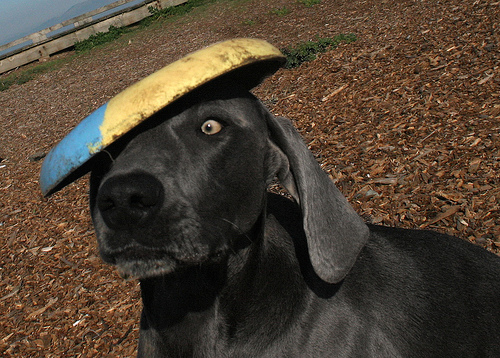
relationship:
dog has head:
[84, 81, 499, 357] [85, 92, 374, 285]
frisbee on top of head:
[38, 37, 285, 201] [85, 92, 374, 285]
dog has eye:
[84, 81, 499, 357] [198, 116, 226, 134]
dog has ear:
[84, 81, 499, 357] [263, 107, 370, 283]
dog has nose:
[84, 81, 499, 357] [96, 169, 164, 230]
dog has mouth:
[84, 81, 499, 357] [100, 241, 247, 274]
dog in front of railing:
[84, 81, 499, 357] [0, 1, 194, 74]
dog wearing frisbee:
[84, 81, 499, 357] [38, 37, 285, 201]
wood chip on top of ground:
[434, 189, 459, 203] [0, 0, 499, 357]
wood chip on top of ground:
[322, 84, 348, 102] [0, 0, 499, 357]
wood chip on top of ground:
[445, 44, 460, 52] [0, 0, 499, 357]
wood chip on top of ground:
[25, 296, 59, 324] [0, 0, 499, 357]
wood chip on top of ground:
[114, 323, 135, 345] [0, 0, 499, 357]